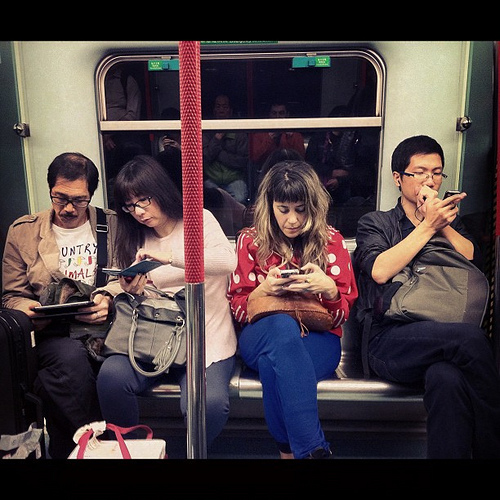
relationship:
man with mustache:
[3, 151, 127, 433] [54, 210, 80, 220]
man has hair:
[3, 151, 127, 433] [31, 145, 108, 197]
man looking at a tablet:
[3, 151, 127, 433] [24, 288, 93, 324]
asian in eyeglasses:
[353, 115, 494, 409] [401, 168, 449, 183]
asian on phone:
[353, 115, 494, 409] [427, 187, 459, 224]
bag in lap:
[247, 290, 336, 332] [245, 321, 339, 362]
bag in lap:
[247, 290, 336, 332] [235, 300, 342, 343]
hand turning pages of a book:
[128, 247, 170, 266] [101, 261, 158, 282]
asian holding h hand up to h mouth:
[353, 115, 494, 409] [415, 182, 438, 203]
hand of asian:
[413, 185, 438, 215] [353, 115, 494, 409]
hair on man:
[392, 134, 452, 169] [369, 121, 483, 449]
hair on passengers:
[267, 161, 323, 211] [228, 157, 356, 458]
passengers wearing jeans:
[228, 157, 356, 458] [235, 312, 342, 452]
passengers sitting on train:
[228, 157, 356, 458] [6, 5, 481, 498]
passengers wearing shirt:
[228, 157, 356, 458] [226, 221, 358, 339]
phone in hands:
[273, 266, 303, 284] [251, 256, 331, 302]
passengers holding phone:
[228, 157, 356, 458] [273, 266, 303, 284]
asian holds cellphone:
[353, 115, 494, 409] [442, 187, 463, 198]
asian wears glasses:
[353, 115, 494, 409] [399, 169, 448, 182]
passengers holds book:
[98, 152, 239, 450] [101, 261, 158, 278]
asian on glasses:
[353, 115, 494, 409] [401, 169, 441, 186]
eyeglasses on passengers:
[122, 197, 152, 212] [98, 152, 239, 450]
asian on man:
[353, 115, 494, 409] [3, 151, 127, 433]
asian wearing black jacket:
[353, 115, 494, 409] [356, 201, 476, 332]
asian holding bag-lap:
[353, 115, 494, 409] [377, 235, 491, 326]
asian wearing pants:
[353, 115, 494, 409] [389, 307, 486, 480]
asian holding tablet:
[353, 115, 494, 409] [21, 264, 98, 324]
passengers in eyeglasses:
[98, 152, 239, 450] [122, 196, 155, 212]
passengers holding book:
[98, 152, 239, 450] [102, 256, 161, 282]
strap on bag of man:
[93, 204, 108, 286] [3, 151, 127, 433]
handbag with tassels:
[104, 282, 189, 377] [147, 318, 184, 374]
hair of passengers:
[267, 161, 323, 199] [228, 157, 356, 458]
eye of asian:
[412, 168, 425, 178] [353, 115, 494, 409]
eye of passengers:
[295, 202, 306, 213] [228, 157, 356, 458]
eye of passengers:
[273, 204, 293, 223] [228, 157, 356, 458]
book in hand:
[101, 261, 158, 278] [115, 269, 147, 296]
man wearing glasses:
[3, 151, 127, 433] [47, 188, 94, 209]